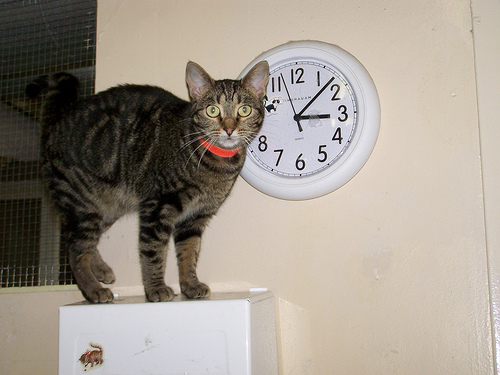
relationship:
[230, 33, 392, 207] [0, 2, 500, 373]
clock on wall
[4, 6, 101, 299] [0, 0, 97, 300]
screen on wall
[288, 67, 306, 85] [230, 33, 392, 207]
number on a clock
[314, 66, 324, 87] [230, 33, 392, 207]
number on a clock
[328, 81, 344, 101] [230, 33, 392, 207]
number on a clock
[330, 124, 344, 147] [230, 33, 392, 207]
number on a clock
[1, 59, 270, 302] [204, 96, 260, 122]
cat has eyes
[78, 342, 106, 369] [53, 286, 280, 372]
mouse image on metal box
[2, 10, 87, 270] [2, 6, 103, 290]
metal grate over opening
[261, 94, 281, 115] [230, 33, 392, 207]
dog on clock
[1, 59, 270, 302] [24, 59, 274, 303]
cat has stripes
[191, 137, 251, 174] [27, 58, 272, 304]
red collar worn by cat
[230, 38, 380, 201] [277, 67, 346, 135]
clock has hands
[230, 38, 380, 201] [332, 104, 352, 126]
clock has three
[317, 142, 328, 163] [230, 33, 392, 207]
number five on clock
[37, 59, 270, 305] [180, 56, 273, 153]
cat has head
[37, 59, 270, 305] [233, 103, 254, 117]
cat has eye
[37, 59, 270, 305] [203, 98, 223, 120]
cat has eye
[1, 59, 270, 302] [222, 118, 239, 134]
cat has nose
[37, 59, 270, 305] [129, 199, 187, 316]
cat has leg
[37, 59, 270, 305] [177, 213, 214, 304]
cat has leg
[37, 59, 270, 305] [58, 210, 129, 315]
cat has leg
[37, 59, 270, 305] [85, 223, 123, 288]
cat has leg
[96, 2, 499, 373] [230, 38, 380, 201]
wall has clock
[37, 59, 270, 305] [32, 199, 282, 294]
cat has legs